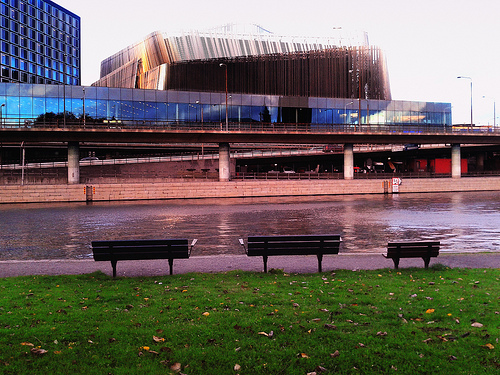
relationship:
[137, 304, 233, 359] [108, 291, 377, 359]
leaves on ground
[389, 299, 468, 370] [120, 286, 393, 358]
leaves on ground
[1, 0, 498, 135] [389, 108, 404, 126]
sky reflected window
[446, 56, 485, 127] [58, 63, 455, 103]
lights line rooftop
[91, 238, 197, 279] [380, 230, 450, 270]
bench and bench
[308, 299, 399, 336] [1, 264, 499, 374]
leaves strewn across grass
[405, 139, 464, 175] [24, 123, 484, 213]
truck parked garage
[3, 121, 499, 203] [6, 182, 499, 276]
garage reflected water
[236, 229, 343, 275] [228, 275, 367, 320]
bench near grass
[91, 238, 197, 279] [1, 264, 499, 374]
bench near grass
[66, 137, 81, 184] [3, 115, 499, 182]
support pillar to bridge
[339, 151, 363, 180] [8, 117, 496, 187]
pillar to bridge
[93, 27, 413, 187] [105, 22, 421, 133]
building has design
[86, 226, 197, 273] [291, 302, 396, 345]
bench in grass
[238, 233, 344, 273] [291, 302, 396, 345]
bench in grass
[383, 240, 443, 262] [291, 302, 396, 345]
bench in grass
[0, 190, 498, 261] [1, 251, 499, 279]
water in front of sidewalk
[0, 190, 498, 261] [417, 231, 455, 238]
water has ripple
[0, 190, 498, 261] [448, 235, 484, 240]
water has ripple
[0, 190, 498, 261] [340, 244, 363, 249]
water has ripple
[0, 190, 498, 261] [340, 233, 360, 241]
water has ripple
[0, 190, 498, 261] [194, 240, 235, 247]
water has ripple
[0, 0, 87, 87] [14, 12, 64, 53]
building has windows